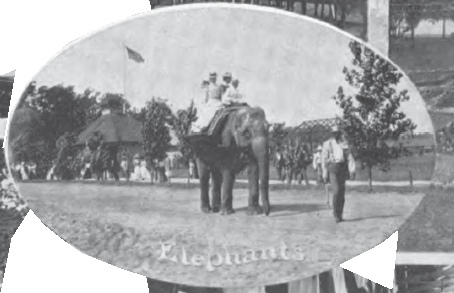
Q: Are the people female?
A: No, they are both male and female.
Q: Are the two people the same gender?
A: No, they are both male and female.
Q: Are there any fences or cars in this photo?
A: No, there are no cars or fences.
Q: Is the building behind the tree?
A: Yes, the building is behind the tree.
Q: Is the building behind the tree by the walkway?
A: Yes, the building is behind the tree.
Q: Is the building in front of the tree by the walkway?
A: No, the building is behind the tree.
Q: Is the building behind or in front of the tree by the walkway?
A: The building is behind the tree.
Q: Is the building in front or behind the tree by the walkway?
A: The building is behind the tree.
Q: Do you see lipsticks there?
A: No, there are no lipsticks.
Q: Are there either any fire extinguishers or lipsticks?
A: No, there are no lipsticks or fire extinguishers.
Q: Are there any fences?
A: No, there are no fences.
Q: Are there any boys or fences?
A: No, there are no fences or boys.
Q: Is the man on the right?
A: Yes, the man is on the right of the image.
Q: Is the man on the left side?
A: No, the man is on the right of the image.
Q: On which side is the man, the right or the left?
A: The man is on the right of the image.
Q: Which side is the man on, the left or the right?
A: The man is on the right of the image.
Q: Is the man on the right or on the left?
A: The man is on the right of the image.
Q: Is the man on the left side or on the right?
A: The man is on the right of the image.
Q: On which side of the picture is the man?
A: The man is on the right of the image.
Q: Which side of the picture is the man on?
A: The man is on the right of the image.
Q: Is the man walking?
A: Yes, the man is walking.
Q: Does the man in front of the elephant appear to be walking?
A: Yes, the man is walking.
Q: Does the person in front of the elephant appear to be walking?
A: Yes, the man is walking.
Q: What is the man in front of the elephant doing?
A: The man is walking.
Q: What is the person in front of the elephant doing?
A: The man is walking.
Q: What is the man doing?
A: The man is walking.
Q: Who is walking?
A: The man is walking.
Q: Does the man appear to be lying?
A: No, the man is walking.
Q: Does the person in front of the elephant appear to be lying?
A: No, the man is walking.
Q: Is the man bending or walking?
A: The man is walking.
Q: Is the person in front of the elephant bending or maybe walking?
A: The man is walking.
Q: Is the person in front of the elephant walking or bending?
A: The man is walking.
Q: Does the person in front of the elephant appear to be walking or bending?
A: The man is walking.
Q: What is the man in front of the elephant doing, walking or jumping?
A: The man is walking.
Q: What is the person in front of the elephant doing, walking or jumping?
A: The man is walking.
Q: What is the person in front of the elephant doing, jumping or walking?
A: The man is walking.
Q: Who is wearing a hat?
A: The man is wearing a hat.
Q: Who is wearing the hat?
A: The man is wearing a hat.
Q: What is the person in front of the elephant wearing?
A: The man is wearing a hat.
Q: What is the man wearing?
A: The man is wearing a hat.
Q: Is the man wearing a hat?
A: Yes, the man is wearing a hat.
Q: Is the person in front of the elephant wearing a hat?
A: Yes, the man is wearing a hat.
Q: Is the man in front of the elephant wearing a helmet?
A: No, the man is wearing a hat.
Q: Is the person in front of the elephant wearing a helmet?
A: No, the man is wearing a hat.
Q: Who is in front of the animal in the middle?
A: The man is in front of the elephant.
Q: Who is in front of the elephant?
A: The man is in front of the elephant.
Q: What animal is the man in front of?
A: The man is in front of the elephant.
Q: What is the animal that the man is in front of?
A: The animal is an elephant.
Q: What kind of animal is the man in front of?
A: The man is in front of the elephant.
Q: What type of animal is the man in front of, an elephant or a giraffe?
A: The man is in front of an elephant.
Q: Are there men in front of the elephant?
A: Yes, there is a man in front of the elephant.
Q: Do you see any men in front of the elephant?
A: Yes, there is a man in front of the elephant.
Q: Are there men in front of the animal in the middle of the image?
A: Yes, there is a man in front of the elephant.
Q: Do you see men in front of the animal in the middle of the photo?
A: Yes, there is a man in front of the elephant.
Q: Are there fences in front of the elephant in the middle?
A: No, there is a man in front of the elephant.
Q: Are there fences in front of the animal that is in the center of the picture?
A: No, there is a man in front of the elephant.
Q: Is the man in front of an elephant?
A: Yes, the man is in front of an elephant.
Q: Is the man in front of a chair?
A: No, the man is in front of an elephant.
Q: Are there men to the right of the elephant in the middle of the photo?
A: Yes, there is a man to the right of the elephant.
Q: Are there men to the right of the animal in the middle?
A: Yes, there is a man to the right of the elephant.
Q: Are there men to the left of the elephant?
A: No, the man is to the right of the elephant.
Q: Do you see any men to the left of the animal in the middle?
A: No, the man is to the right of the elephant.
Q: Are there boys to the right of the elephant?
A: No, there is a man to the right of the elephant.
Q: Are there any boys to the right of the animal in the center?
A: No, there is a man to the right of the elephant.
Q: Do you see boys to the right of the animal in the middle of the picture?
A: No, there is a man to the right of the elephant.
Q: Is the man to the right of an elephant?
A: Yes, the man is to the right of an elephant.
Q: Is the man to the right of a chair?
A: No, the man is to the right of an elephant.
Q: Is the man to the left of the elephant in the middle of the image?
A: No, the man is to the right of the elephant.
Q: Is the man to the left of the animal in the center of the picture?
A: No, the man is to the right of the elephant.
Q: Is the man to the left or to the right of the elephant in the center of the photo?
A: The man is to the right of the elephant.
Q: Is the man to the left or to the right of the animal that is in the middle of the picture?
A: The man is to the right of the elephant.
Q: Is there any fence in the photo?
A: No, there are no fences.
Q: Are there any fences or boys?
A: No, there are no fences or boys.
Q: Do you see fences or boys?
A: No, there are no fences or boys.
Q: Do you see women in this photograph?
A: Yes, there is a woman.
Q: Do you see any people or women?
A: Yes, there is a woman.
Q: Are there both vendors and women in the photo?
A: No, there is a woman but no vendors.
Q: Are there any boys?
A: No, there are no boys.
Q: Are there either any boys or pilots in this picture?
A: No, there are no boys or pilots.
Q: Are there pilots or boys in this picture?
A: No, there are no boys or pilots.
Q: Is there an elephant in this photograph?
A: Yes, there is an elephant.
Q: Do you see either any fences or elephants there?
A: Yes, there is an elephant.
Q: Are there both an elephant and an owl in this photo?
A: No, there is an elephant but no owls.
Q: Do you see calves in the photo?
A: No, there are no calves.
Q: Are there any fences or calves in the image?
A: No, there are no calves or fences.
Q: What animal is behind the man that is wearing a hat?
A: The animal is an elephant.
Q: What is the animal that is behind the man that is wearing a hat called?
A: The animal is an elephant.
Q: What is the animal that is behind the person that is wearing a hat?
A: The animal is an elephant.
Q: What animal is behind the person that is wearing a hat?
A: The animal is an elephant.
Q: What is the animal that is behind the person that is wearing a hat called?
A: The animal is an elephant.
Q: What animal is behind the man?
A: The animal is an elephant.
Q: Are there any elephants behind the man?
A: Yes, there is an elephant behind the man.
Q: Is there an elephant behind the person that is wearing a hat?
A: Yes, there is an elephant behind the man.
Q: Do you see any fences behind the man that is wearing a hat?
A: No, there is an elephant behind the man.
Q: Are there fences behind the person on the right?
A: No, there is an elephant behind the man.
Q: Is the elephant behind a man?
A: Yes, the elephant is behind a man.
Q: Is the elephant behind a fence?
A: No, the elephant is behind a man.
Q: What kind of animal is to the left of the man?
A: The animal is an elephant.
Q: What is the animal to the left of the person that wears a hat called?
A: The animal is an elephant.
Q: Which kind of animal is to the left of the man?
A: The animal is an elephant.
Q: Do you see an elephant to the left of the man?
A: Yes, there is an elephant to the left of the man.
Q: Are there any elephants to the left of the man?
A: Yes, there is an elephant to the left of the man.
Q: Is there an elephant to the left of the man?
A: Yes, there is an elephant to the left of the man.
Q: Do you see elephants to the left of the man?
A: Yes, there is an elephant to the left of the man.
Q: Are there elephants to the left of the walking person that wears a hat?
A: Yes, there is an elephant to the left of the man.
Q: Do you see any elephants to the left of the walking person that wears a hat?
A: Yes, there is an elephant to the left of the man.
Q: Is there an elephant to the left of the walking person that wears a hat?
A: Yes, there is an elephant to the left of the man.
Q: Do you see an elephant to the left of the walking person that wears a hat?
A: Yes, there is an elephant to the left of the man.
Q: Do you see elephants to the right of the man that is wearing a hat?
A: No, the elephant is to the left of the man.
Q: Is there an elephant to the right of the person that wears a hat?
A: No, the elephant is to the left of the man.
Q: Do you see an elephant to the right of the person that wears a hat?
A: No, the elephant is to the left of the man.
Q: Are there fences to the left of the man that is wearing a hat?
A: No, there is an elephant to the left of the man.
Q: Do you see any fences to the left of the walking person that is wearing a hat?
A: No, there is an elephant to the left of the man.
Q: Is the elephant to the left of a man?
A: Yes, the elephant is to the left of a man.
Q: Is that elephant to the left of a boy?
A: No, the elephant is to the left of a man.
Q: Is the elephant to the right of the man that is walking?
A: No, the elephant is to the left of the man.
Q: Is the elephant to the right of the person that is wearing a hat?
A: No, the elephant is to the left of the man.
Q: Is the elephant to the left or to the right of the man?
A: The elephant is to the left of the man.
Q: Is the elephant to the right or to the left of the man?
A: The elephant is to the left of the man.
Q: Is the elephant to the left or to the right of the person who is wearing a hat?
A: The elephant is to the left of the man.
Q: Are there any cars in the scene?
A: No, there are no cars.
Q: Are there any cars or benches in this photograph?
A: No, there are no cars or benches.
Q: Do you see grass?
A: Yes, there is grass.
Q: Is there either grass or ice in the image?
A: Yes, there is grass.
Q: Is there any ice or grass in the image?
A: Yes, there is grass.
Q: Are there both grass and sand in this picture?
A: No, there is grass but no sand.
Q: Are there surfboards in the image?
A: No, there are no surfboards.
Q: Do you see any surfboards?
A: No, there are no surfboards.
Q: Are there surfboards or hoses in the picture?
A: No, there are no surfboards or hoses.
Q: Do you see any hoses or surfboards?
A: No, there are no surfboards or hoses.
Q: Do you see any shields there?
A: No, there are no shields.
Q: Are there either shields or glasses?
A: No, there are no shields or glasses.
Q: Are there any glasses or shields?
A: No, there are no shields or glasses.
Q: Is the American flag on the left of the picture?
A: Yes, the American flag is on the left of the image.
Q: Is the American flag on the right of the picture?
A: No, the American flag is on the left of the image.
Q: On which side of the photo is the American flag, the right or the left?
A: The American flag is on the left of the image.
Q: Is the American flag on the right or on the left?
A: The American flag is on the left of the image.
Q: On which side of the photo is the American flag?
A: The American flag is on the left of the image.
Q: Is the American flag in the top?
A: Yes, the American flag is in the top of the image.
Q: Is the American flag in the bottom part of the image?
A: No, the American flag is in the top of the image.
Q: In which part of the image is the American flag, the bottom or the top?
A: The American flag is in the top of the image.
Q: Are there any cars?
A: No, there are no cars.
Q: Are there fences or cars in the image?
A: No, there are no cars or fences.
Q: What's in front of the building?
A: The tree is in front of the building.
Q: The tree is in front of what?
A: The tree is in front of the building.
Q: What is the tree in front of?
A: The tree is in front of the building.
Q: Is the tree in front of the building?
A: Yes, the tree is in front of the building.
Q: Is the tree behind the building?
A: No, the tree is in front of the building.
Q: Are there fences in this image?
A: No, there are no fences.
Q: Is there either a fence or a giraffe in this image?
A: No, there are no fences or giraffes.